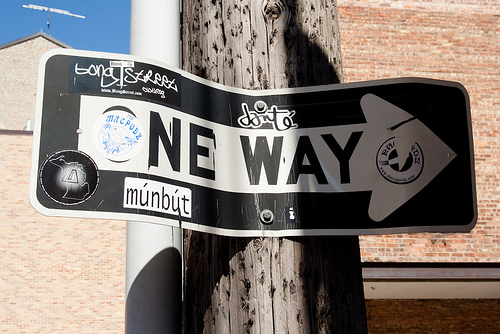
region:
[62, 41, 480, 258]
Bent one-way sign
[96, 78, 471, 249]
Black and white one-way sign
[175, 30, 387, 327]
One-way sign attached to telephone pole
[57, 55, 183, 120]
Graffiti on sign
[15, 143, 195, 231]
Stickers on sign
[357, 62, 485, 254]
Bricked wall behind sign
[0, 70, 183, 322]
Brick building on right side of sign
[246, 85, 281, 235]
Screws attaching sign to telephone pole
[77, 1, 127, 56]
Clear blue sky and no clouds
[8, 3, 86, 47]
Antenna on top of building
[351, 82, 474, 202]
white arrow pointing right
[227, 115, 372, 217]
word on the sign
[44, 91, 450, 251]
bent sign on the pole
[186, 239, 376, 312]
pole in the photo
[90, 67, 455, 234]
light and dark sign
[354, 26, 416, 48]
bricks in the background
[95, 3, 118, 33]
blue sky above the building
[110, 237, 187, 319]
shadow on the pole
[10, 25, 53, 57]
top of the building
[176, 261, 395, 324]
bottom part of the pole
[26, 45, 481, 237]
broken and graffiti covered sign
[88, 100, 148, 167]
white sticker over O on sign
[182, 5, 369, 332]
brown post behind sign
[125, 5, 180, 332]
white pole behind sign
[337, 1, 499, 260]
brick building on right of sign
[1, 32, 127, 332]
brick building on left of sign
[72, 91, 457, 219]
white arrow pointing right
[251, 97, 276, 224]
bolts connecting sign to post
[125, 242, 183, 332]
shadow on white post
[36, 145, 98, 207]
black circle sticker on corner of sign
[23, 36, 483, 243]
a street sign.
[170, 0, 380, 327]
a wooden pole with a sign on it.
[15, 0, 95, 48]
a roof top antenna.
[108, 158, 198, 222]
A sticker on a street sign.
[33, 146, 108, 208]
A stick on the left side of a sign.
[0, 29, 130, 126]
A building with a pointy roof.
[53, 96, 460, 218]
a large white arrow.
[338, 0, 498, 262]
a brick building.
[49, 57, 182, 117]
graffiti on a sign.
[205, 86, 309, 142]
graffiti above a large arrow.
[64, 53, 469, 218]
black and white sign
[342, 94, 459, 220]
tip of the arrow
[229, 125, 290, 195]
the letter W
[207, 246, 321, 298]
pole under the sign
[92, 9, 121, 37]
blue sky above land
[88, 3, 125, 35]
blue sky with no clouds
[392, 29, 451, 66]
brick wall behind sign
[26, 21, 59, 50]
top part of building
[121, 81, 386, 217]
bent sign on pole